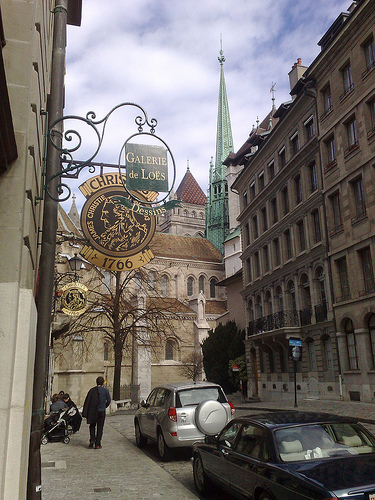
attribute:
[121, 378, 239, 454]
car — parked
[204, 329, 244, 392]
bushes —  leafy,  green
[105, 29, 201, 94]
clouds —  white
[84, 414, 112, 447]
pants — black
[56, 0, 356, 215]
clouds —  white 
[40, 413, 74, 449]
stroller — black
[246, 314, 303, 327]
fence —  black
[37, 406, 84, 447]
carriege —  baby's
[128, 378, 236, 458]
car — silver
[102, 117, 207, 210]
sign — black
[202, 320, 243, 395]
bush —  green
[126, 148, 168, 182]
lettering — golden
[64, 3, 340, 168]
sky —  blue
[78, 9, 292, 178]
sky —  blue